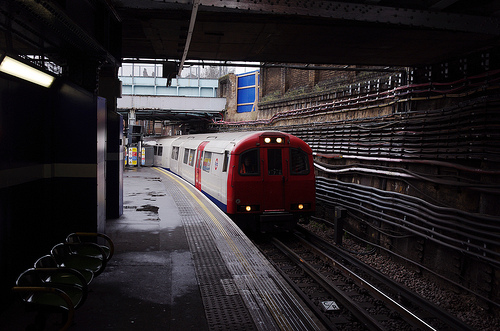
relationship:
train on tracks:
[152, 129, 318, 237] [268, 211, 457, 327]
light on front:
[296, 202, 306, 210] [226, 130, 318, 217]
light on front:
[296, 200, 306, 210] [226, 130, 318, 217]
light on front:
[244, 199, 255, 212] [226, 130, 318, 217]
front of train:
[226, 130, 318, 217] [148, 128, 318, 240]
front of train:
[226, 130, 321, 223] [132, 126, 319, 228]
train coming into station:
[129, 117, 322, 232] [2, 1, 499, 330]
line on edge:
[152, 165, 244, 260] [156, 166, 326, 328]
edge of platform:
[156, 166, 326, 328] [44, 163, 332, 327]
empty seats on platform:
[6, 222, 117, 322] [1, 155, 324, 329]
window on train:
[235, 146, 266, 180] [124, 119, 336, 237]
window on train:
[265, 143, 283, 178] [132, 126, 319, 228]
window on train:
[235, 147, 263, 178] [111, 102, 341, 245]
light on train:
[296, 202, 306, 210] [148, 121, 323, 238]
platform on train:
[44, 163, 332, 327] [148, 128, 318, 240]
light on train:
[296, 202, 306, 210] [162, 126, 307, 223]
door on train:
[264, 148, 290, 208] [202, 105, 331, 213]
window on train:
[235, 147, 263, 178] [132, 126, 319, 228]